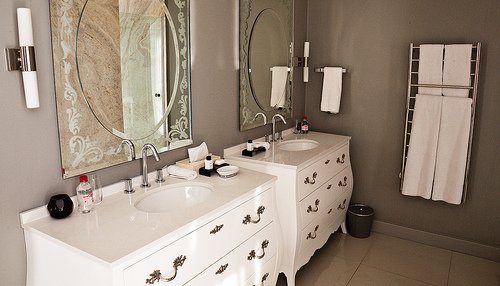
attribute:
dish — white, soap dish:
[223, 148, 237, 178]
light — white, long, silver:
[13, 12, 98, 154]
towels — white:
[398, 42, 478, 207]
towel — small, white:
[320, 62, 344, 120]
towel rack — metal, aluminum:
[399, 38, 480, 207]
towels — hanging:
[401, 89, 474, 204]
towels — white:
[390, 24, 479, 227]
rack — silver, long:
[397, 42, 481, 195]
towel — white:
[320, 67, 341, 114]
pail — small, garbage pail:
[346, 200, 380, 236]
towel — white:
[439, 95, 471, 206]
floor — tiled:
[348, 236, 436, 283]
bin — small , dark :
[346, 203, 373, 236]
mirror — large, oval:
[53, 2, 191, 158]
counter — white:
[78, 213, 152, 250]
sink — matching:
[38, 157, 268, 257]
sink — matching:
[218, 113, 351, 194]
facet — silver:
[271, 113, 286, 151]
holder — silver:
[311, 63, 348, 74]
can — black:
[342, 198, 380, 238]